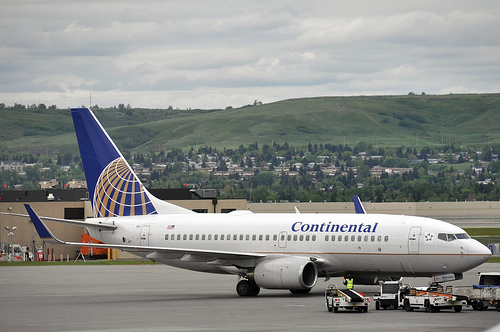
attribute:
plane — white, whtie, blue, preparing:
[0, 106, 494, 298]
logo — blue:
[290, 219, 379, 234]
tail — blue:
[70, 106, 159, 219]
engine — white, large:
[253, 256, 319, 291]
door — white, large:
[407, 225, 423, 254]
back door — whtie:
[139, 223, 151, 249]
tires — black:
[235, 279, 313, 295]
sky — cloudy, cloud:
[0, 1, 499, 113]